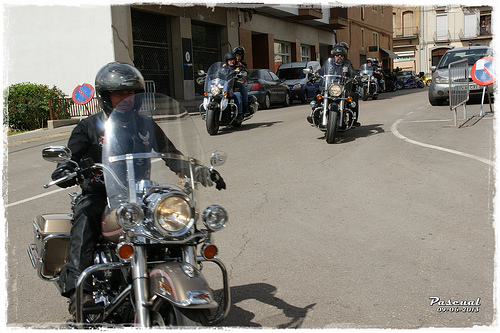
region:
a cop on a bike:
[45, 90, 190, 317]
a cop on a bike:
[270, 20, 418, 202]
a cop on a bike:
[305, 36, 372, 243]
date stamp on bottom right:
[422, 292, 497, 326]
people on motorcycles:
[28, 32, 413, 331]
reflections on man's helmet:
[95, 55, 145, 118]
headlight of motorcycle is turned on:
[141, 177, 201, 239]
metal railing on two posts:
[438, 53, 475, 141]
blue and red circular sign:
[68, 73, 94, 108]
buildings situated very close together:
[110, 2, 397, 107]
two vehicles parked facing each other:
[230, 45, 322, 115]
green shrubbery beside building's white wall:
[5, 6, 152, 136]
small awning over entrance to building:
[367, 25, 402, 95]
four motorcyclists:
[76, 33, 411, 163]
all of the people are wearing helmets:
[69, 24, 447, 179]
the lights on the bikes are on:
[128, 159, 278, 273]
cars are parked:
[251, 69, 438, 91]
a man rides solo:
[17, 90, 287, 291]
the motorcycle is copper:
[66, 186, 238, 329]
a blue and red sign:
[43, 75, 94, 115]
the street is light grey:
[291, 174, 475, 312]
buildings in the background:
[159, 19, 484, 68]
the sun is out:
[28, 79, 449, 300]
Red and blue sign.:
[61, 86, 99, 110]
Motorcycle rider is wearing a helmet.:
[82, 59, 150, 104]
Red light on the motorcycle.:
[111, 236, 139, 263]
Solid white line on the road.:
[400, 141, 485, 167]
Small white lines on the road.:
[392, 85, 444, 115]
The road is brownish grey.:
[368, 215, 436, 254]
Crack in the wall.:
[105, 31, 143, 75]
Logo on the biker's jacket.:
[128, 129, 158, 146]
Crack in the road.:
[219, 226, 268, 277]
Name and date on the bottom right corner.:
[430, 296, 497, 318]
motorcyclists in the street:
[19, 38, 420, 325]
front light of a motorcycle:
[144, 190, 202, 241]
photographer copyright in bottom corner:
[424, 290, 494, 322]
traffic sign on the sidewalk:
[65, 70, 96, 109]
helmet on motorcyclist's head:
[89, 56, 154, 121]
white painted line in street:
[391, 127, 491, 179]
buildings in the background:
[337, 7, 494, 47]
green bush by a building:
[2, 76, 68, 131]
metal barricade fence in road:
[442, 52, 478, 135]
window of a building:
[430, 11, 454, 43]